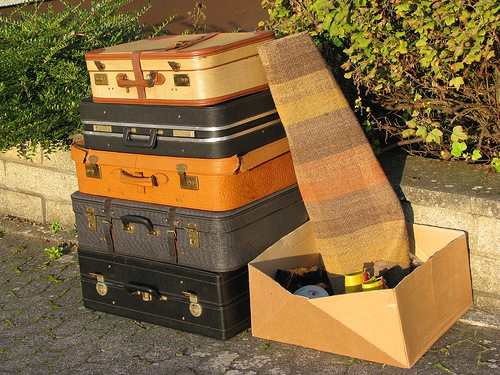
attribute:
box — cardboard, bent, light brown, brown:
[248, 216, 475, 370]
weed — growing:
[46, 244, 64, 259]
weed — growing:
[52, 222, 64, 235]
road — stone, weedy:
[2, 222, 499, 372]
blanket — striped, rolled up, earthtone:
[255, 29, 412, 293]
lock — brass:
[183, 221, 202, 252]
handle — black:
[125, 281, 160, 302]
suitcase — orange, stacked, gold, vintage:
[71, 141, 297, 213]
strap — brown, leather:
[134, 33, 220, 101]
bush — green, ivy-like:
[2, 1, 205, 152]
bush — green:
[259, 0, 500, 166]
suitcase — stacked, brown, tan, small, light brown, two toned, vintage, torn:
[84, 29, 278, 108]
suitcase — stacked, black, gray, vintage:
[80, 89, 287, 158]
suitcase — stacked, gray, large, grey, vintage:
[68, 182, 310, 272]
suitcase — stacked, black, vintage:
[76, 244, 251, 339]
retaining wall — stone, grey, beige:
[5, 133, 499, 317]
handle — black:
[119, 213, 158, 236]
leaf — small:
[45, 149, 56, 153]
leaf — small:
[16, 152, 26, 160]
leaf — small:
[61, 146, 67, 151]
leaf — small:
[69, 29, 79, 39]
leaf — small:
[32, 35, 38, 45]